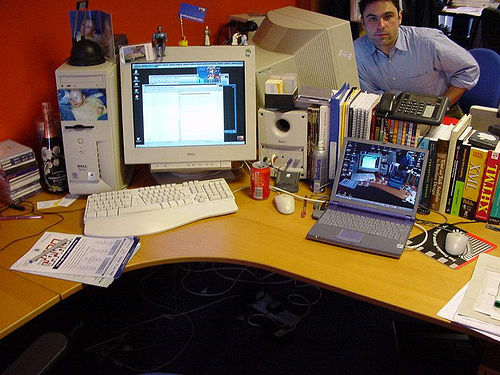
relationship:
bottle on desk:
[35, 102, 70, 201] [4, 181, 497, 290]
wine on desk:
[31, 93, 68, 195] [4, 181, 497, 290]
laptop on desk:
[313, 130, 435, 255] [4, 181, 497, 290]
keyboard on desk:
[80, 178, 237, 234] [4, 181, 497, 290]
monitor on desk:
[118, 41, 263, 175] [4, 181, 497, 290]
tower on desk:
[53, 58, 120, 194] [4, 181, 497, 290]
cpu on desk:
[54, 54, 126, 196] [4, 181, 497, 290]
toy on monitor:
[147, 24, 169, 59] [118, 41, 263, 175]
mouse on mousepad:
[443, 228, 468, 254] [413, 222, 497, 271]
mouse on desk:
[443, 228, 468, 254] [4, 181, 497, 290]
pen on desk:
[300, 191, 309, 221] [4, 181, 497, 290]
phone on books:
[375, 90, 451, 126] [342, 109, 497, 227]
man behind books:
[348, 3, 481, 97] [342, 109, 497, 227]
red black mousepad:
[476, 236, 483, 242] [413, 222, 497, 271]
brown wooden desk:
[261, 223, 289, 246] [4, 181, 497, 290]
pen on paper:
[300, 191, 309, 221] [14, 229, 142, 289]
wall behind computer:
[2, 6, 71, 62] [47, 44, 259, 183]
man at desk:
[348, 3, 481, 97] [4, 181, 497, 290]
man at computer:
[348, 3, 481, 97] [47, 44, 259, 183]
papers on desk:
[9, 230, 142, 289] [4, 181, 497, 290]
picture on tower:
[70, 9, 117, 65] [53, 58, 120, 194]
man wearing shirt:
[348, 3, 481, 97] [356, 39, 476, 96]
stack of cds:
[1, 149, 43, 198] [2, 138, 44, 201]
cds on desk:
[2, 138, 44, 201] [4, 181, 497, 290]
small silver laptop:
[314, 209, 414, 257] [313, 130, 435, 255]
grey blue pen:
[58, 238, 69, 245] [27, 238, 67, 265]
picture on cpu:
[70, 9, 117, 65] [54, 54, 126, 196]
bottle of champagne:
[35, 102, 70, 201] [31, 101, 71, 195]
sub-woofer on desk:
[256, 109, 305, 181] [4, 181, 497, 290]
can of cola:
[249, 161, 271, 202] [249, 161, 271, 203]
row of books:
[419, 135, 497, 218] [342, 109, 497, 227]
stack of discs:
[1, 149, 43, 198] [2, 134, 45, 202]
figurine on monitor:
[146, 22, 170, 63] [118, 41, 263, 175]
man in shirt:
[348, 3, 481, 97] [356, 39, 476, 96]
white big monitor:
[289, 19, 320, 45] [118, 41, 263, 175]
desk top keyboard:
[4, 181, 497, 290] [80, 178, 237, 234]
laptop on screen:
[313, 130, 435, 255] [347, 141, 414, 212]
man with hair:
[348, 3, 481, 97] [357, 3, 370, 12]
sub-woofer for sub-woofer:
[256, 109, 305, 181] [258, 108, 309, 179]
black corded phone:
[405, 104, 419, 117] [378, 83, 448, 126]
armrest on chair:
[10, 330, 70, 374] [465, 46, 499, 113]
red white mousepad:
[476, 236, 483, 242] [413, 222, 497, 271]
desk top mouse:
[4, 181, 497, 290] [443, 228, 468, 254]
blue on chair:
[483, 82, 492, 96] [465, 46, 499, 113]